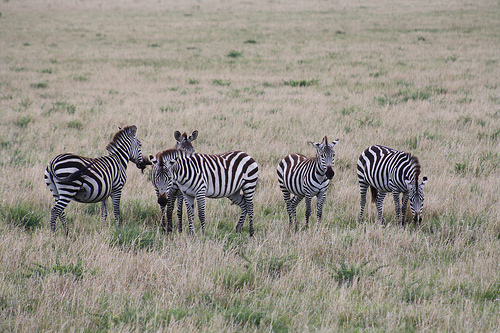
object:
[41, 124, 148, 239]
zebra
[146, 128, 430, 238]
four zebras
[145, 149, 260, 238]
zebra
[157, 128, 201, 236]
zebra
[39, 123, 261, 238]
three zebras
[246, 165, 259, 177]
stripes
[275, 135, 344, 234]
zebra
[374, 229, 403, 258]
dead grass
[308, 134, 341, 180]
head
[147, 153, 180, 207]
head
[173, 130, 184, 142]
ears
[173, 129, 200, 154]
head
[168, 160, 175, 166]
stripes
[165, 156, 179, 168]
ear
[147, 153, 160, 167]
ear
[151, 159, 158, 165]
stripes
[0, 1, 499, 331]
grass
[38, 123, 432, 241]
others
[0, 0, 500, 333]
ground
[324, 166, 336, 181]
snout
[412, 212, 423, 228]
snout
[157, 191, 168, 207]
snout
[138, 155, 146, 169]
snout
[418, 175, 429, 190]
ear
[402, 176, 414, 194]
ear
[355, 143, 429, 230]
zebra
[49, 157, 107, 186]
tail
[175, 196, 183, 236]
leg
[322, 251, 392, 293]
bush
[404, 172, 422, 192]
neck